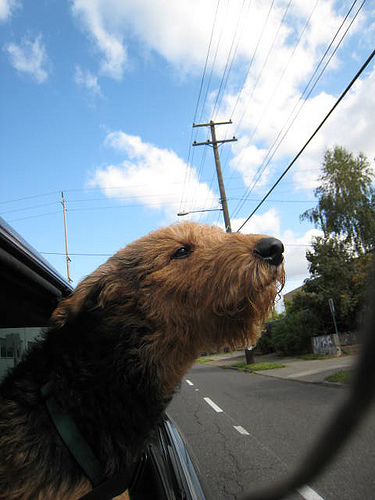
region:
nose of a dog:
[251, 234, 284, 265]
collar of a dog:
[37, 379, 115, 492]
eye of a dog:
[173, 244, 192, 262]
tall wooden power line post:
[189, 116, 256, 365]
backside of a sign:
[326, 298, 344, 356]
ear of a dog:
[53, 260, 125, 327]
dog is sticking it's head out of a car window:
[0, 213, 300, 499]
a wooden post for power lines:
[60, 191, 74, 285]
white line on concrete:
[183, 377, 196, 386]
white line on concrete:
[203, 396, 223, 414]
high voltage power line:
[2, 183, 62, 199]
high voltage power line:
[1, 199, 61, 214]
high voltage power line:
[1, 211, 60, 222]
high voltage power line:
[67, 182, 184, 187]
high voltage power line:
[65, 194, 185, 200]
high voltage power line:
[63, 203, 201, 213]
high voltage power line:
[228, 191, 326, 203]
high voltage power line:
[196, 2, 230, 123]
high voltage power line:
[209, 14, 249, 119]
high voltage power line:
[230, 2, 290, 136]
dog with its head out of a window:
[0, 217, 287, 499]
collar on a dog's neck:
[17, 364, 112, 487]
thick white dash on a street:
[231, 422, 251, 435]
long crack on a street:
[183, 400, 290, 498]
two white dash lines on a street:
[224, 416, 326, 499]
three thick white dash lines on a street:
[201, 389, 354, 498]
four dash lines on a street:
[184, 376, 329, 498]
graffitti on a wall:
[311, 335, 336, 347]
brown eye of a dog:
[166, 243, 195, 259]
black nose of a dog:
[249, 236, 284, 267]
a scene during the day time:
[4, 6, 373, 496]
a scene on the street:
[2, 2, 373, 497]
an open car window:
[0, 219, 210, 496]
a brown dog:
[0, 205, 295, 498]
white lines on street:
[169, 362, 332, 498]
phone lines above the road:
[35, 10, 372, 342]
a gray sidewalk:
[220, 341, 374, 399]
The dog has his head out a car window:
[2, 200, 370, 496]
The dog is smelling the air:
[1, 207, 372, 495]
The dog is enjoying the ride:
[15, 212, 353, 492]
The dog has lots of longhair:
[0, 210, 372, 477]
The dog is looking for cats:
[2, 203, 317, 497]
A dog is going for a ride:
[0, 197, 371, 477]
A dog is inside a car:
[4, 212, 355, 483]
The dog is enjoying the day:
[22, 202, 370, 472]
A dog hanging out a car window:
[6, 223, 282, 499]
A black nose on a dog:
[257, 236, 285, 261]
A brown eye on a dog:
[170, 243, 192, 257]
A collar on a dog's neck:
[42, 383, 111, 485]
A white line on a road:
[203, 393, 222, 413]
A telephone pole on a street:
[191, 119, 236, 233]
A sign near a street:
[327, 295, 338, 331]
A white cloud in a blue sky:
[94, 128, 215, 219]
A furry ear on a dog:
[48, 268, 110, 322]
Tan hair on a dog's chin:
[207, 314, 265, 351]